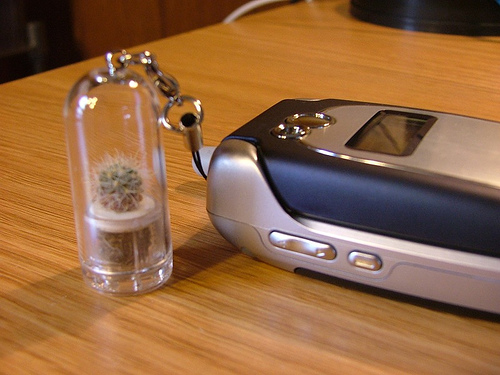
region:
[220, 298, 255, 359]
part of a table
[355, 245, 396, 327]
part of a phone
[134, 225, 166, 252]
part of a gklass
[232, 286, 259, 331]
paert of a table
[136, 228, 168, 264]
part of a glass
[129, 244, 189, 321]
part of a glass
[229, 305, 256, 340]
part of a table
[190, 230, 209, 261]
part of a shade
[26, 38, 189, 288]
the holder is made of glass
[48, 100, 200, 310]
it has a white ball inside it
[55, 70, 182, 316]
it is transparent and clear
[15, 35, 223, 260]
it is chained to a mobile phone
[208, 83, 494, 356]
the phone has two buttons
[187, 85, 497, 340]
it is grey and black in clour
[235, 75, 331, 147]
it has a camera on the front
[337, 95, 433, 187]
it has a screen on the front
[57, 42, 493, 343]
they are placed on the table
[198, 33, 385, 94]
the table is brown in colour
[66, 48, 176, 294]
mini keychain terrarium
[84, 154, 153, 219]
mini cactus with little thorns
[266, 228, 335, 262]
cell phone control button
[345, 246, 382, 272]
cell phone function button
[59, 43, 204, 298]
cell phone keychain decoration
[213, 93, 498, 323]
flip type silver and blue cellphone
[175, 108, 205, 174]
cellphone strap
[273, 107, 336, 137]
cellphone front camera lens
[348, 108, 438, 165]
cellphone front viewscreen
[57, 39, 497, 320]
cellphone with mini terrarium attached by a chain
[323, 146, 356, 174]
part of a cellphone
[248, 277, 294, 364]
part of a table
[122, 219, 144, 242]
part of a glass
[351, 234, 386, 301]
part of a button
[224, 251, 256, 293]
part of a shade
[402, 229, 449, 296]
edge of a phone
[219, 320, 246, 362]
part of a tablw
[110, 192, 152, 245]
part of a glass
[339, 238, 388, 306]
part of a phone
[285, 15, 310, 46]
part of a table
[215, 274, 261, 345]
part of a table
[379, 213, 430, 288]
part of a phone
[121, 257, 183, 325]
dge of a glass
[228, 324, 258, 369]
part of a table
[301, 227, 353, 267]
part of a button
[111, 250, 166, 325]
part of a glass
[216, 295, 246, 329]
part of a table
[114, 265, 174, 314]
edge of a glass